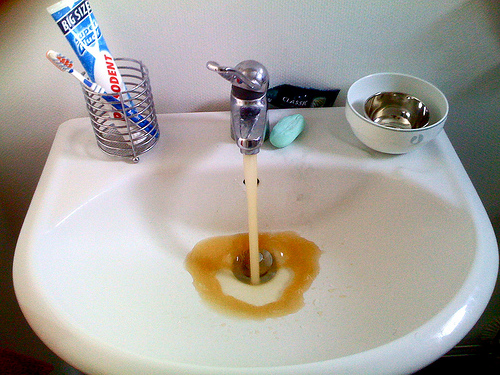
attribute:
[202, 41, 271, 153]
faucet — silver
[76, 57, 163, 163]
toothbrush caddy — metal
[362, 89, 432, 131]
bowl — metal, small, stainless steel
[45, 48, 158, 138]
toothbrush — blue, white, red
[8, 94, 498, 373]
sink — white, small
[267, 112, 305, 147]
soap — small, green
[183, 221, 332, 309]
water — dirty, brown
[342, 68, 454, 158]
bowl — ceramic, small, white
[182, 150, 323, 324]
water — disgusting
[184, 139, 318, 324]
water — gross, brown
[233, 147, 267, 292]
water — dirty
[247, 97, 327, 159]
soap — green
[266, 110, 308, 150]
soap — green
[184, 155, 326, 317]
water — brown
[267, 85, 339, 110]
paper — black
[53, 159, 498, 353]
sink — white, ceramic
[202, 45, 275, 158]
faucet — chrome